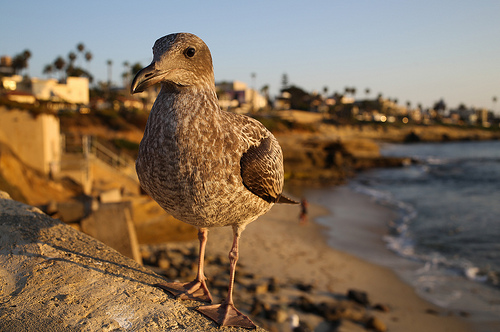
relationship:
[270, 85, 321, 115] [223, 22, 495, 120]
buildings in background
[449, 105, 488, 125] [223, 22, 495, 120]
buildings in background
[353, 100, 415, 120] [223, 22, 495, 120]
buildings in background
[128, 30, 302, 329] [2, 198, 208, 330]
bird sitting on rock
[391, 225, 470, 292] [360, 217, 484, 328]
wave crashing on shore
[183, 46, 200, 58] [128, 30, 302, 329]
eye on top of bird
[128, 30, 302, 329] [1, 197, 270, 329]
bird perched on rock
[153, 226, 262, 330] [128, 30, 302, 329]
legs attached to bird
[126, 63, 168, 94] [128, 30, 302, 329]
beak attached to bird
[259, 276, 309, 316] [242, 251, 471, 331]
rocks are on beach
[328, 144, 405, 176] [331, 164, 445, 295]
rocks are on shoreline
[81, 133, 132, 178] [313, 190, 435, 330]
stairs leads to beach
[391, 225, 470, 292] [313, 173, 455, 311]
wave breaking on shore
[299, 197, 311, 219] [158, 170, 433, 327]
person standing on beach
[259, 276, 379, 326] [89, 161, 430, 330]
rocks are on sand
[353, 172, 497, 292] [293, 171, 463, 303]
waves are on beach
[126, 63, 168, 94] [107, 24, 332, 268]
beak on bird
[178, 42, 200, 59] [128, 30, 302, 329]
eye on bird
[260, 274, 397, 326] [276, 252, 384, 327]
debris on sand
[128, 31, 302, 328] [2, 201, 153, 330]
bird standing on a rock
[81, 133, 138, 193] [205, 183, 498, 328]
stairs from sand